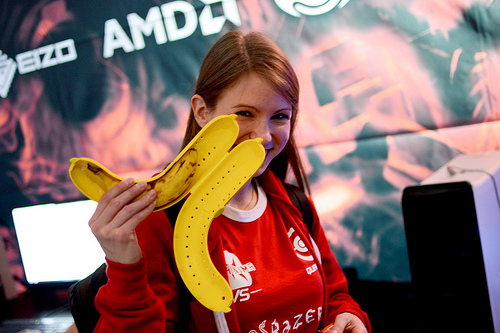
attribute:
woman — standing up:
[80, 23, 382, 332]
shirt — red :
[205, 178, 335, 332]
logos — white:
[209, 221, 340, 331]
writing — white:
[101, 2, 233, 54]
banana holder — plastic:
[67, 104, 264, 317]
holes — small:
[175, 135, 220, 247]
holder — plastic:
[64, 108, 269, 319]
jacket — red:
[93, 173, 365, 331]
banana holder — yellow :
[52, 107, 268, 314]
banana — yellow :
[84, 163, 209, 210]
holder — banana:
[193, 136, 230, 259]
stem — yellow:
[82, 160, 110, 180]